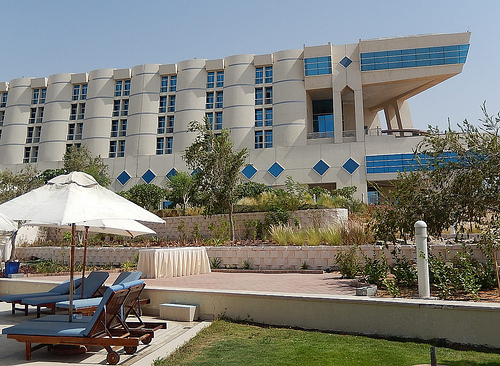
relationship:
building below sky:
[5, 30, 484, 218] [1, 2, 499, 132]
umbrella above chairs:
[4, 169, 163, 244] [6, 258, 152, 359]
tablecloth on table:
[134, 246, 213, 278] [136, 243, 214, 278]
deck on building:
[363, 91, 484, 141] [5, 30, 484, 218]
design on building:
[312, 158, 331, 176] [5, 30, 484, 218]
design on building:
[341, 157, 361, 175] [5, 30, 484, 218]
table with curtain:
[134, 242, 213, 280] [134, 244, 213, 279]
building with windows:
[10, 27, 484, 240] [251, 59, 278, 157]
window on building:
[27, 81, 51, 106] [10, 27, 484, 240]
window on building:
[67, 79, 90, 101] [10, 27, 484, 240]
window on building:
[111, 72, 136, 98] [10, 27, 484, 240]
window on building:
[155, 70, 180, 93] [10, 27, 484, 240]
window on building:
[201, 62, 227, 89] [10, 27, 484, 240]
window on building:
[251, 59, 278, 85] [10, 27, 484, 240]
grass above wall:
[262, 219, 309, 240] [224, 242, 326, 271]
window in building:
[251, 83, 276, 107] [217, 62, 323, 181]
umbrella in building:
[4, 169, 163, 244] [106, 69, 366, 187]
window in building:
[251, 55, 276, 93] [5, 30, 484, 218]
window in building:
[249, 123, 276, 157] [5, 30, 484, 218]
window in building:
[247, 61, 276, 87] [5, 30, 484, 218]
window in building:
[151, 81, 185, 117] [5, 30, 484, 218]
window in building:
[249, 105, 277, 127] [5, 30, 484, 218]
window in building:
[253, 122, 280, 150] [5, 30, 484, 218]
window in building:
[253, 101, 279, 128] [5, 30, 484, 218]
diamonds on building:
[237, 159, 289, 189] [67, 57, 366, 211]